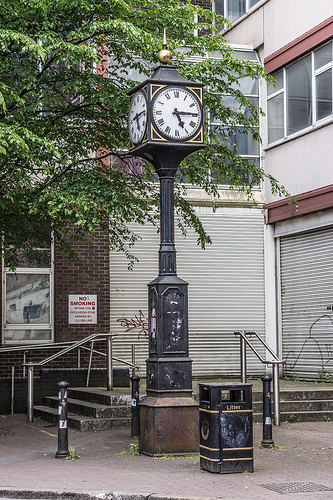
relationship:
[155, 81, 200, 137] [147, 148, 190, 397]
clock on top of post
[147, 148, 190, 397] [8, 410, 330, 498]
post in ground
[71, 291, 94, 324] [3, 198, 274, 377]
sign on wall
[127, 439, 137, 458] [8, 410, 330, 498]
weed in ground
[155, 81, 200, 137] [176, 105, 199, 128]
clock has hands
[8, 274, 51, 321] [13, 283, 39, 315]
window has refelection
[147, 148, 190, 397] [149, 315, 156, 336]
post has stickers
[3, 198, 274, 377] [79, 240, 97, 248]
wall has bricks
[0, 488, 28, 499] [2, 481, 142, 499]
edge of curb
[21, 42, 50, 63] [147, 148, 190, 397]
leaves near post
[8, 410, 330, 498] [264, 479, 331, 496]
ground has grate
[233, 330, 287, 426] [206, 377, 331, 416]
railing near steps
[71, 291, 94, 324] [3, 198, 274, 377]
sign on side of wall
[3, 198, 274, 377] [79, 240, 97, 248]
wall made of bricks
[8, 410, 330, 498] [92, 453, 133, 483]
ground made of bricks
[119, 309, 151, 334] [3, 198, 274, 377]
graffiti on wall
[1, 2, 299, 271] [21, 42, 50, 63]
tree has leaves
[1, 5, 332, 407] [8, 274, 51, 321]
building has window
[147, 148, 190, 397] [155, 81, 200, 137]
post has clock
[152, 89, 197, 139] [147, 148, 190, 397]
clock face on top of post